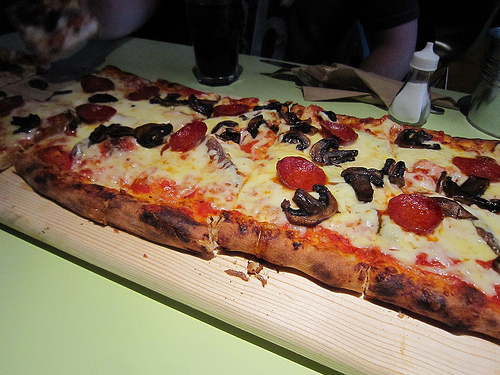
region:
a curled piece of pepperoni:
[276, 156, 326, 188]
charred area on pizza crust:
[137, 205, 193, 237]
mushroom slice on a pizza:
[279, 183, 337, 229]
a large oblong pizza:
[15, 55, 497, 344]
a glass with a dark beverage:
[190, 0, 242, 84]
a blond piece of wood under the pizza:
[0, 164, 498, 374]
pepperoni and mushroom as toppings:
[277, 155, 339, 225]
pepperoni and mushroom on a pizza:
[279, 156, 335, 223]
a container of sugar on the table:
[387, 38, 440, 129]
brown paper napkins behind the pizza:
[279, 58, 471, 120]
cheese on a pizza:
[173, 140, 235, 192]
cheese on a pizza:
[122, 145, 177, 190]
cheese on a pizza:
[75, 144, 134, 198]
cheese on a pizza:
[233, 157, 278, 235]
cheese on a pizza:
[340, 202, 367, 244]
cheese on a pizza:
[382, 217, 428, 249]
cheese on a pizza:
[456, 225, 488, 256]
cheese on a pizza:
[154, 102, 184, 130]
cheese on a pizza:
[123, 101, 150, 123]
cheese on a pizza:
[60, 91, 92, 113]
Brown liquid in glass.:
[186, 19, 233, 69]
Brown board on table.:
[129, 253, 229, 325]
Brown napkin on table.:
[329, 63, 376, 114]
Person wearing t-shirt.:
[313, 8, 432, 54]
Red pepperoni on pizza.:
[398, 187, 439, 238]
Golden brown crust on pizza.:
[241, 227, 341, 289]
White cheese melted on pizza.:
[372, 223, 409, 259]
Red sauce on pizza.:
[416, 257, 455, 283]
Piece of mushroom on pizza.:
[293, 181, 339, 241]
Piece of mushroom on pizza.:
[351, 165, 376, 204]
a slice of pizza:
[216, 95, 398, 297]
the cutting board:
[0, 59, 499, 374]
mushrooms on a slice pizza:
[280, 104, 437, 227]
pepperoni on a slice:
[273, 114, 362, 191]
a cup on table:
[186, 7, 246, 86]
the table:
[1, 34, 499, 371]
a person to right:
[97, 0, 423, 76]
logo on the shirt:
[237, 3, 288, 65]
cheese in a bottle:
[241, 119, 386, 240]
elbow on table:
[93, 4, 142, 43]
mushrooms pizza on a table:
[19, 67, 499, 335]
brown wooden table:
[2, 62, 486, 374]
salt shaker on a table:
[385, 42, 440, 129]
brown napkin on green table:
[294, 60, 457, 112]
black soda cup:
[190, 3, 245, 86]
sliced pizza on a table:
[24, 60, 499, 337]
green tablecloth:
[7, 19, 494, 374]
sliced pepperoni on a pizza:
[62, 71, 499, 229]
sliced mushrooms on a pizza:
[40, 74, 498, 233]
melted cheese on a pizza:
[20, 68, 498, 295]